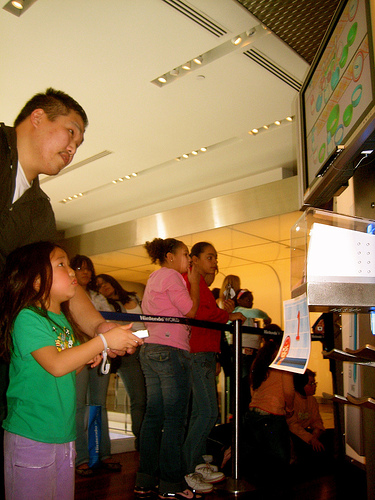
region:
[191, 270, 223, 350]
The red jacket the girl is wearing.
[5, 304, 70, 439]
The green shirt the girl is wearing.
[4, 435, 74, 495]
The purple pants the girl is wearing.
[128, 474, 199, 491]
The black and pink sneakers the girl is wearing.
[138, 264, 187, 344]
The pink shirt the girl is wearing.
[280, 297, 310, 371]
The paper with the number 1 on it.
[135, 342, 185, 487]
The jeans the girl in the pink shirt is wearing.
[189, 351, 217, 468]
The jeans the girl in the red jacket is wearing.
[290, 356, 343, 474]
The lady sitting on the floor in the yellow sweater.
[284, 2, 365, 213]
The flat screen t.v.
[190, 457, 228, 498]
white and orange snaeakers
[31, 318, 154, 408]
white wii controller on wrist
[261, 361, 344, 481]
person sitting on floor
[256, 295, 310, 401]
calender with number 1 on it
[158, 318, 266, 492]
slender black pole with shine on it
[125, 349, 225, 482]
two pairs of blue jeans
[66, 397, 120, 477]
blue and white bag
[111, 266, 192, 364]
person wearing a pink shirt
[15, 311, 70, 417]
person wearing green shirt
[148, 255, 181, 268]
small ear ring in ear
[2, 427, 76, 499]
purple pants on the girl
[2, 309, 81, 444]
green shirt on the girl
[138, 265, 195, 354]
pink shirt on the girl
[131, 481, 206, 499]
girl wearing black and pink shoes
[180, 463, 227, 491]
girl wearing white shoes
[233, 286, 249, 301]
pink headband on the girl's head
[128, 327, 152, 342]
wii remote in the girl's hand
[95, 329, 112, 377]
white wii remote wristband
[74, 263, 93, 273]
woman wearing glasses on her face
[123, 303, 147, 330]
woman wearing a white shirt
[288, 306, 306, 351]
The orange number 1 on the paper.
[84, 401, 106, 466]
The blue bag between the lady's legs.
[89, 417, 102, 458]
The white writing on the blue bag.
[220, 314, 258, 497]
The silver pole in front of the group.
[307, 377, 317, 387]
The glasses the lady in the yellow sweater is wearing.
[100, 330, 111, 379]
The strap of the Wii game controller.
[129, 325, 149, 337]
The Wii controller in the girl's hand.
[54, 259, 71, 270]
The eyes of the little girl with the Wii remote in her hand.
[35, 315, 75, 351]
The design on the little girl's green shirt.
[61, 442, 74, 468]
The purple strings on the little girl's purple pants.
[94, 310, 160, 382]
hand holding a wii mote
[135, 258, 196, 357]
pink shirt on a woman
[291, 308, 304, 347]
red number one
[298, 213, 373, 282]
wii console in a glass box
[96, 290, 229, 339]
barrier rope with writing on it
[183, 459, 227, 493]
white sneakers on a woman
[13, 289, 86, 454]
green shirt on a girl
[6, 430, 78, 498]
lavender pants on a girl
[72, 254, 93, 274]
glasses on a woman's face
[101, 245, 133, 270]
white ceiling tiles